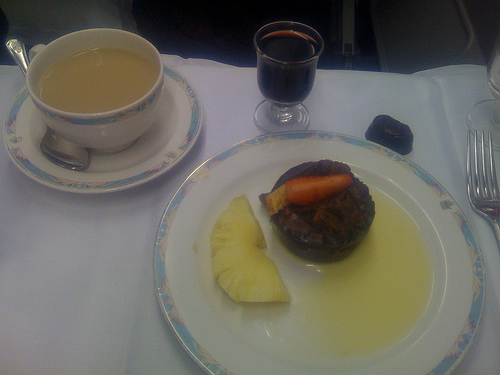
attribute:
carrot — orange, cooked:
[266, 169, 352, 219]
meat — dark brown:
[269, 158, 376, 262]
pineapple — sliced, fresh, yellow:
[207, 193, 294, 305]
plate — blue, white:
[148, 130, 485, 374]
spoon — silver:
[5, 38, 90, 171]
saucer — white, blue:
[4, 63, 201, 195]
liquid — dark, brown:
[256, 29, 318, 104]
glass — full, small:
[250, 20, 324, 133]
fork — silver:
[465, 125, 499, 253]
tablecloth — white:
[1, 60, 499, 374]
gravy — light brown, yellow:
[38, 47, 159, 115]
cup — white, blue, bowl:
[24, 23, 166, 156]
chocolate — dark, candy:
[363, 110, 414, 157]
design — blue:
[153, 131, 484, 374]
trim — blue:
[5, 64, 202, 192]